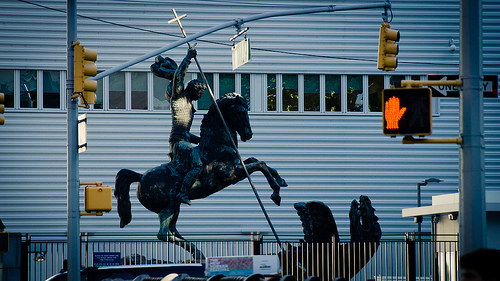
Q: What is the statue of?
A: A man riding a horsre.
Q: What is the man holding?
A: A cross on a long pole.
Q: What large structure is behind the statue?
A: A building.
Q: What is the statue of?
A: A man on a horse.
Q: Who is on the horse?
A: A man.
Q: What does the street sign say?
A: No walking.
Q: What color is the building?
A: White.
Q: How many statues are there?
A: 1.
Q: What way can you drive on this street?
A: Left.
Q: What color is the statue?
A: Black.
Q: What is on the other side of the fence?
A: A street.